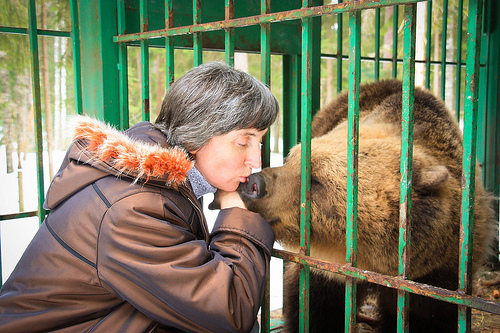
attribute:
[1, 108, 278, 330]
jacket — brown, shiny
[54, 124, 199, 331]
coat — brown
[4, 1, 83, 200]
trees — young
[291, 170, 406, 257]
bars — green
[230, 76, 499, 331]
bear — brown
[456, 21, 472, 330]
metal bars — green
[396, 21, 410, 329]
metal bars — green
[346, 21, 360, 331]
metal bars — green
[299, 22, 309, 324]
metal bars — green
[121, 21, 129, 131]
metal bars — green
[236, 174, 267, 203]
nose — black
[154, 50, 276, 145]
hair — gray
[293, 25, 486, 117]
metal — rusty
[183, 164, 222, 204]
collar — heather grey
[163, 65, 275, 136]
hair — short, salt and pepper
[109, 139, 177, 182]
fur — orange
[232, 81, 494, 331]
grizzly bear — large, brown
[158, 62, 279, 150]
grey/black hair — grey, black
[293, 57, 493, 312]
enclosure — metal, green